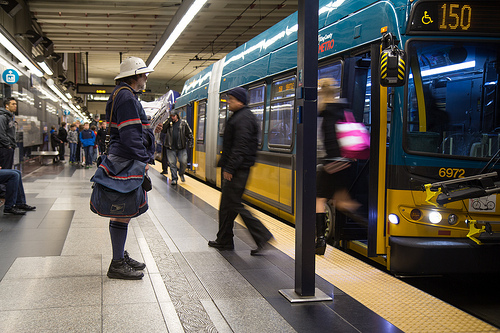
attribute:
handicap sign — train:
[417, 7, 435, 27]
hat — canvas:
[104, 59, 152, 80]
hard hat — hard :
[113, 55, 153, 79]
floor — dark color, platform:
[164, 276, 299, 331]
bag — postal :
[85, 152, 156, 221]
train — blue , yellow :
[172, 23, 498, 287]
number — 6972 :
[438, 165, 465, 180]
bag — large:
[89, 153, 154, 220]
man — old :
[90, 55, 158, 279]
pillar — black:
[297, 0, 315, 300]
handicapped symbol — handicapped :
[420, 12, 432, 24]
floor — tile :
[19, 251, 181, 315]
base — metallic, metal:
[280, 285, 332, 305]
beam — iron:
[294, 0, 317, 296]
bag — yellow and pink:
[336, 108, 371, 157]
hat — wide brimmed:
[113, 55, 153, 80]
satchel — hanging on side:
[51, 160, 158, 236]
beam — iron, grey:
[289, 0, 320, 303]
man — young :
[1, 97, 41, 219]